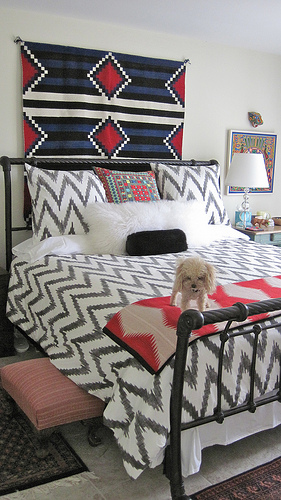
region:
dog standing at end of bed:
[9, 129, 279, 498]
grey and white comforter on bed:
[6, 218, 279, 480]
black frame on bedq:
[165, 282, 276, 498]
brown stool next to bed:
[0, 346, 118, 464]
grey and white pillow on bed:
[13, 145, 241, 242]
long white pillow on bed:
[77, 197, 205, 245]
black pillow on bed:
[119, 222, 195, 262]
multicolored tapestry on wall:
[3, 18, 216, 257]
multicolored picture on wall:
[213, 96, 279, 232]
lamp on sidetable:
[212, 141, 277, 244]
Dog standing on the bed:
[158, 229, 251, 320]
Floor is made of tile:
[81, 457, 114, 488]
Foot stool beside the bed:
[0, 353, 134, 448]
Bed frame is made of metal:
[148, 301, 259, 452]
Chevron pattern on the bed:
[52, 282, 110, 351]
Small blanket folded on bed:
[119, 277, 194, 373]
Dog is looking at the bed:
[158, 251, 217, 312]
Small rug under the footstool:
[8, 435, 93, 498]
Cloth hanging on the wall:
[6, 24, 228, 174]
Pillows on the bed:
[36, 173, 241, 252]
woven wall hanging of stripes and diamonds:
[18, 34, 185, 159]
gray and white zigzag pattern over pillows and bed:
[10, 161, 275, 474]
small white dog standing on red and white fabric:
[94, 254, 275, 370]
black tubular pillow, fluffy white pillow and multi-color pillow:
[94, 162, 220, 249]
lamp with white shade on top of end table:
[223, 129, 268, 237]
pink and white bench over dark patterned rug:
[0, 332, 89, 489]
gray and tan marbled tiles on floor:
[4, 417, 275, 496]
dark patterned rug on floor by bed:
[184, 456, 275, 493]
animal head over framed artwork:
[224, 108, 272, 192]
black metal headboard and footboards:
[0, 149, 278, 494]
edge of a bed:
[165, 450, 181, 482]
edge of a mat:
[223, 492, 225, 494]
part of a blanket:
[141, 443, 147, 455]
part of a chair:
[53, 389, 56, 394]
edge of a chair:
[45, 396, 53, 416]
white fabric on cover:
[90, 367, 95, 371]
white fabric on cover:
[115, 371, 122, 376]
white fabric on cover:
[150, 399, 155, 408]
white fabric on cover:
[149, 440, 154, 447]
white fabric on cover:
[78, 343, 84, 353]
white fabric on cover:
[78, 327, 90, 334]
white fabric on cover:
[114, 345, 126, 366]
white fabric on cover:
[124, 433, 133, 445]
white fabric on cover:
[50, 330, 56, 335]